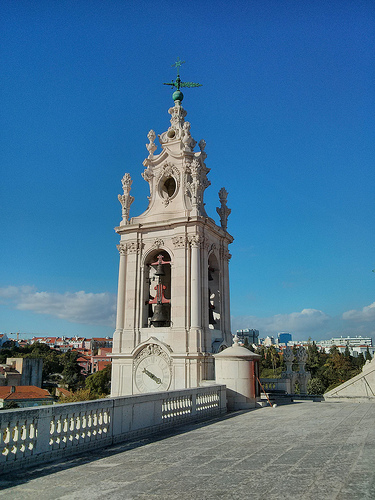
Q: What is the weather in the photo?
A: Mostly sunny.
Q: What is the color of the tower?
A: White.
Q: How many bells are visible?
A: Two.